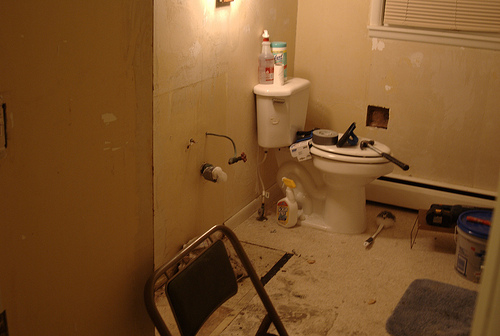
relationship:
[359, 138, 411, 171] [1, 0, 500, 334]
hammer on top of bathroom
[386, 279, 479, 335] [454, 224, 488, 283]
rug next to bucket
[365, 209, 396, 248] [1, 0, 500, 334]
toilet brush next to bathroom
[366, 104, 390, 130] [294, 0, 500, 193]
hole in wall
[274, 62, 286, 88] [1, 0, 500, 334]
toilet paper on bathroom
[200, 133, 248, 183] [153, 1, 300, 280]
plumbing sticking out of wall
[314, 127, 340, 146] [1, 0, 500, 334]
duct tape on bathroom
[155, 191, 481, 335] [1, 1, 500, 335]
floor in bathroom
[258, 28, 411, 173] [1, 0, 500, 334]
objects on bathroom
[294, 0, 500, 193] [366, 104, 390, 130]
wall has a hole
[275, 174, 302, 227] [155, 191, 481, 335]
spray bottle on floor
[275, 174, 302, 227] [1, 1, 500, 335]
spray bottle in bathroom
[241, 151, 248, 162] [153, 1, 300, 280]
water knob on wall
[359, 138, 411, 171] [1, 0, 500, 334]
hammer on bathroom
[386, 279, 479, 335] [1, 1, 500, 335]
rug in bathroom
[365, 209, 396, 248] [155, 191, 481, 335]
toilet brush on floor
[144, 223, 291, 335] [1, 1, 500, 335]
stool in bathroom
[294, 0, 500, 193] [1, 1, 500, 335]
wall in bathroom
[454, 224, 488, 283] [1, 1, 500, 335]
bucket in bathroom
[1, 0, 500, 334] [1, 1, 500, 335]
bathroom in bathroom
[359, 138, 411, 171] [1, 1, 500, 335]
hammer in bathroom